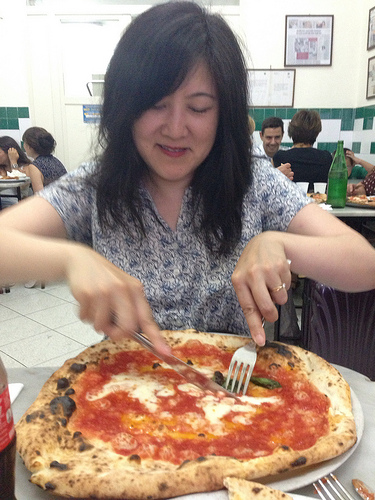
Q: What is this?
A: Pizza.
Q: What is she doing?
A: Cutting pizza.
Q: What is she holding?
A: A fork.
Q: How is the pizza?
A: Large.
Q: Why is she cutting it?
A: To eat it.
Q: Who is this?
A: A woman.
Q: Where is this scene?
A: At a pizza restaurant.